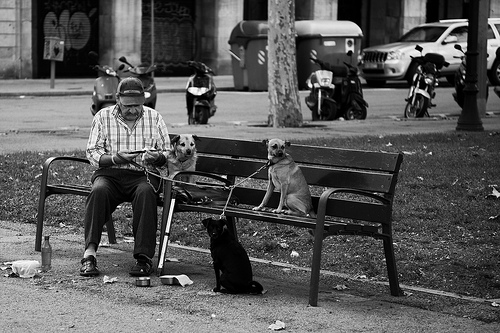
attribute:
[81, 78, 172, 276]
man — sitting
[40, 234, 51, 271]
bottle — plastic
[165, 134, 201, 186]
dog — sitting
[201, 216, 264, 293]
dog — black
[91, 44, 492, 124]
motorcycles — parked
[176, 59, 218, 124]
motorcycle — parked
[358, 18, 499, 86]
suv — parked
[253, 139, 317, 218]
dog — sitting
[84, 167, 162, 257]
pants — black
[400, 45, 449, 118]
motorcycle — parked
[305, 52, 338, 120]
motorcycle — parked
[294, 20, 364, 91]
trash bin — large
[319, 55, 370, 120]
motorcycle — parked